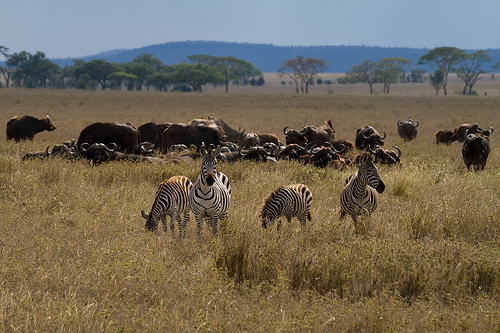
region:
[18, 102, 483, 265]
Animals are in grass.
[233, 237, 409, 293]
Grass is brown color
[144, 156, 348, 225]
Zebra are black and white color.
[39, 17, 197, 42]
Sky is blue color.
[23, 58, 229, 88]
trees are green color.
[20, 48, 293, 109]
Trees are behind the animals.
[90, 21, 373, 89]
Mountain is behind the animal.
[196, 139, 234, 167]
Two pointed ears for zebra.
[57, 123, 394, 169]
Bull are brown color.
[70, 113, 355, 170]
Bull are behind the zebra.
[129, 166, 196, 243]
the zebra is feeding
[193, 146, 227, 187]
the zebras nose is black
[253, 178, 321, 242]
the zebra has his head down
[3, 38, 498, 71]
the mountains in the back ground look blue in color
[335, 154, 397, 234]
the zebra has black and white stripes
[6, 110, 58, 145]
the bison is brown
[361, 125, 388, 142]
this animal has horns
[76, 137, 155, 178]
this animal is laying down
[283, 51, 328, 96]
the trees leaves are brown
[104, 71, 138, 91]
the leaves on this tree are green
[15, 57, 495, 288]
Wild animals are in a field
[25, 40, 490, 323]
Wild animals are in a game reserve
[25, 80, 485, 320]
Wild animals are watching for predators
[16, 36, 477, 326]
Zebra are standing in the grass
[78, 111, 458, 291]
Four Zebra are standing together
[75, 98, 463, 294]
Zebras are looking for food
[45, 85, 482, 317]
Zebras are together with water buffalo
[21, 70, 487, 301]
Animals are together for safety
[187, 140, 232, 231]
A zebra is alerted by something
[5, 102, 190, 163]
Water buffalo are traveling in a herd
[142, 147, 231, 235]
Zebra looking at camera and zebra with head down.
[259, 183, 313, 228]
Black and white zebra with head in the grass between all the others.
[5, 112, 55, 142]
Large brown cow way off the left of the herd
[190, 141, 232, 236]
Black and white zebra looking straight ahead at the camera.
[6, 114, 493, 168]
Herd of cattle in a field.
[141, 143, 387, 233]
Four black and white zebras.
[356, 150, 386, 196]
Head of a zebra to the right of the rest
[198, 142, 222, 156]
Two ears on the zebra second from the left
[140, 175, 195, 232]
Black and white zebra to the left of the herd.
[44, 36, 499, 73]
Gray hazy land in the distance.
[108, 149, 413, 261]
Four black and white zebras standing in a line in the thick grass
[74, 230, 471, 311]
Tall and thick tan colored field of grass and shrubbery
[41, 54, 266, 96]
Thick stand of tall trees with thin trunks and branching green leaves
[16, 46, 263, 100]
Small forest of green trees on the edge of a grass field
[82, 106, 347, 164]
Thick herd of dark colored water buffalo standing together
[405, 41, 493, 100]
Two tall trees with thin trunks and green leaves standing apart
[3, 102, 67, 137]
Dark water buffalo standing alone in a grass field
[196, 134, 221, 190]
Zebra with white ears standing up and a black nose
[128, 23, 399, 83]
Blue looking outline of a mountain range in the distance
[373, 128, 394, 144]
Horns of a water buffalo on it's head